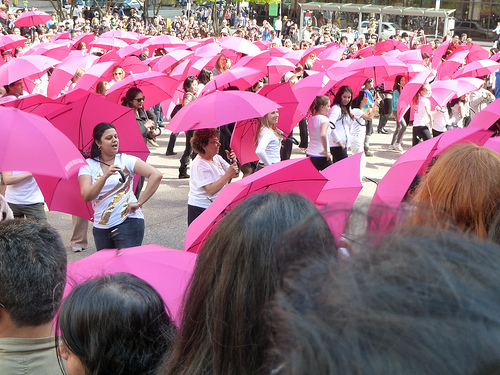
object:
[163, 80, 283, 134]
umbrella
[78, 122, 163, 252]
woman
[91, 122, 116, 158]
hair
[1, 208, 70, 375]
man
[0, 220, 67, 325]
hair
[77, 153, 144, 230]
shirt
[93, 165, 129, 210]
stripe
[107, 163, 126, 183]
handle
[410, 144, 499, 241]
hair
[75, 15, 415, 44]
audience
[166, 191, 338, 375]
person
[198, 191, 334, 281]
head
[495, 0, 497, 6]
cheese